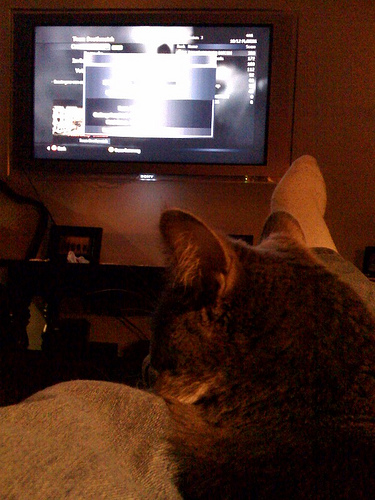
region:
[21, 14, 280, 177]
grey frame on tv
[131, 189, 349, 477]
cat sitting in lap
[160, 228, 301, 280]
cat has brown ears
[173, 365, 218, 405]
cat has light brown neck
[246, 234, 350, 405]
cat has brown head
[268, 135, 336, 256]
person has white socks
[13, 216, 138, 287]
picture frame under tv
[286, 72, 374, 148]
brown wall near tv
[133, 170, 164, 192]
white logo on tv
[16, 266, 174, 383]
black table under tv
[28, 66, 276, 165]
Television is on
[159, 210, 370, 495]
animal relaxing on persons lap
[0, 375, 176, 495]
part of mans jeans, lower right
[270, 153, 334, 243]
man's sock near animal ear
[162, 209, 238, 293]
animals ear pointed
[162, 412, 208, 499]
animal has soft fur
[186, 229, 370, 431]
animal's back is facing camera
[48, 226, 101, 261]
a small frame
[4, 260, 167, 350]
dark wooden table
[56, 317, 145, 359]
items below the table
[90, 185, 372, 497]
The cat is on the lap of the person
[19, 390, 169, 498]
The person is wearing jeans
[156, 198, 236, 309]
The ear of the cat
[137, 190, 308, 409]
The head of the cat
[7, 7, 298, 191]
The TV on the wall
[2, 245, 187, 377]
The stand under the TV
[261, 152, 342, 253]
The foot of the person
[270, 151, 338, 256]
The person has on a white sock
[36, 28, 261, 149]
The TV is on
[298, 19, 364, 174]
The wall is the color white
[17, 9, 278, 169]
television on the wall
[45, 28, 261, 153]
television screen on the wall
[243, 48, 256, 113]
numbers on side of screen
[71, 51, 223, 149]
black box in middle of screen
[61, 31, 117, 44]
white writing on top of screen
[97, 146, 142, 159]
button and writing on screen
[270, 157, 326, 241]
pillow of couch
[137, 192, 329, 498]
back head of cat on couch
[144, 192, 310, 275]
two pointy furry ears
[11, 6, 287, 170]
A television is on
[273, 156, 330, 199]
A person's foot is in the air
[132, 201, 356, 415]
A back of a cat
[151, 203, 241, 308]
Ear of a cat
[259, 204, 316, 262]
Ear of a cat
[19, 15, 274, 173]
The TV is bright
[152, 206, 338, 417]
The cat is laying on the person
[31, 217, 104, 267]
A picture frame on a desk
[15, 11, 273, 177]
The TV is turned on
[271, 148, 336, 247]
The person is wearing a white sock